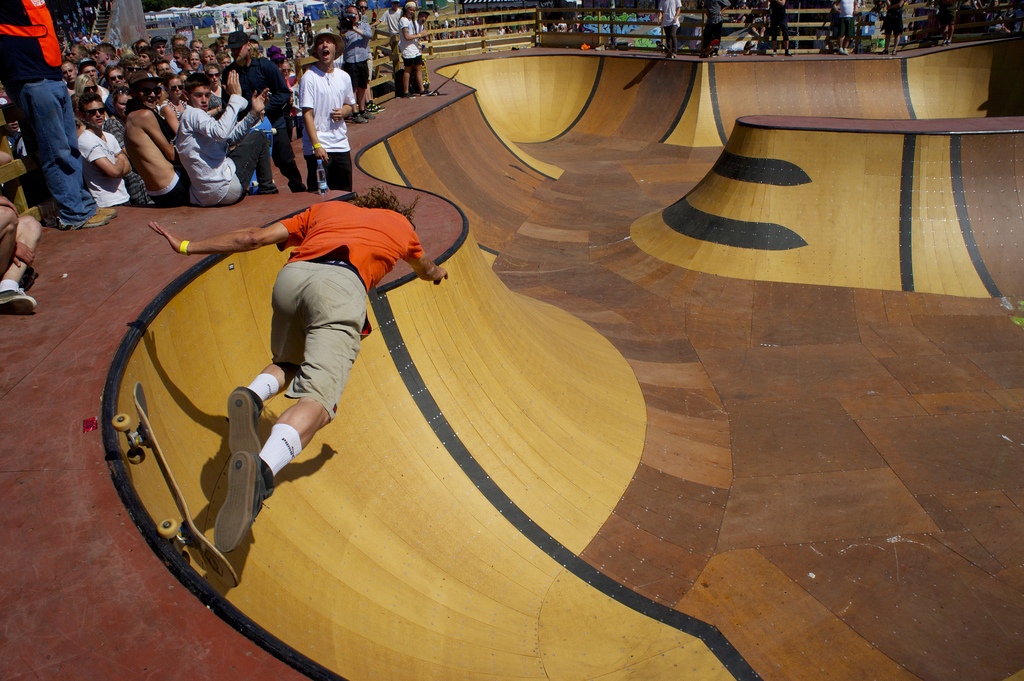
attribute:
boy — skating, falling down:
[124, 155, 472, 575]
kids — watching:
[33, 6, 394, 210]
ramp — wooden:
[34, 29, 1023, 673]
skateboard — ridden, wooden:
[108, 371, 239, 590]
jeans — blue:
[12, 67, 106, 230]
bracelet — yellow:
[175, 238, 194, 252]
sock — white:
[264, 425, 301, 484]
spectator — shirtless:
[122, 61, 195, 211]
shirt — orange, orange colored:
[280, 195, 446, 307]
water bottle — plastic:
[308, 142, 335, 204]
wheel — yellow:
[109, 403, 135, 438]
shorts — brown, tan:
[276, 256, 375, 419]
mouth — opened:
[322, 48, 335, 62]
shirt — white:
[300, 66, 362, 159]